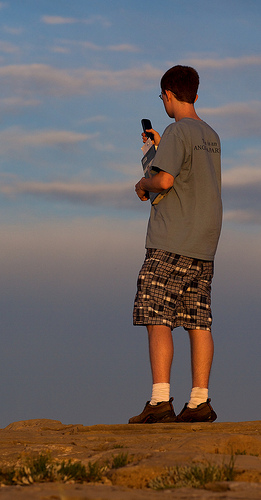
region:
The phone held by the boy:
[139, 117, 155, 143]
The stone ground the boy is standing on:
[0, 416, 260, 498]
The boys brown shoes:
[122, 396, 218, 429]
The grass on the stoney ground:
[2, 442, 242, 494]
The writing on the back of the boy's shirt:
[193, 135, 220, 158]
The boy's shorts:
[130, 247, 218, 335]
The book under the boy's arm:
[140, 136, 172, 212]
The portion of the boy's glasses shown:
[158, 91, 164, 101]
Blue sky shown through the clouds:
[2, 0, 259, 233]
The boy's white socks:
[148, 380, 212, 410]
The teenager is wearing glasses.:
[151, 60, 210, 118]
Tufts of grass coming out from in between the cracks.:
[20, 434, 237, 490]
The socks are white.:
[121, 371, 225, 433]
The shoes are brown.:
[110, 392, 217, 436]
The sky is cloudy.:
[8, 41, 127, 272]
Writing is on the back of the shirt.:
[182, 120, 223, 188]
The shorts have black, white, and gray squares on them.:
[124, 235, 224, 341]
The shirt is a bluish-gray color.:
[127, 116, 237, 265]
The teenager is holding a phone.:
[102, 39, 237, 238]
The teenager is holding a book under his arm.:
[106, 71, 247, 250]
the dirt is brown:
[131, 435, 193, 463]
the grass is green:
[61, 450, 104, 489]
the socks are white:
[145, 370, 224, 406]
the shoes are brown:
[123, 371, 221, 427]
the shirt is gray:
[135, 106, 238, 255]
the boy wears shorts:
[124, 231, 220, 342]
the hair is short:
[152, 60, 214, 110]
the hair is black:
[157, 59, 208, 110]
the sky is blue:
[48, 46, 134, 145]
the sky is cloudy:
[8, 108, 115, 230]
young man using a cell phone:
[129, 61, 225, 423]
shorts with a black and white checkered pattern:
[132, 244, 215, 328]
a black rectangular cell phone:
[137, 114, 155, 141]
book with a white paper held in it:
[135, 137, 173, 205]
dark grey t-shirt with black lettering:
[145, 117, 223, 261]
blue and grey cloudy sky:
[1, 1, 128, 417]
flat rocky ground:
[1, 422, 259, 451]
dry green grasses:
[1, 453, 239, 489]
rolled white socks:
[149, 380, 209, 406]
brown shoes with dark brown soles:
[127, 398, 217, 424]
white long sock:
[148, 376, 171, 405]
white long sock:
[186, 383, 210, 410]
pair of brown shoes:
[115, 393, 216, 428]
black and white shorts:
[122, 243, 221, 339]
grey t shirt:
[129, 115, 229, 263]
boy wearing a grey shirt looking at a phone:
[107, 58, 238, 453]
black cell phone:
[131, 115, 159, 141]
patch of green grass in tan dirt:
[141, 453, 242, 494]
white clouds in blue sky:
[2, 4, 144, 69]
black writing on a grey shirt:
[192, 132, 220, 159]